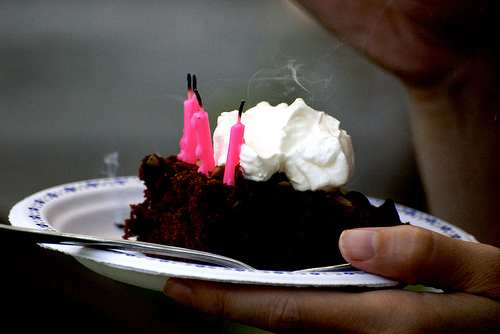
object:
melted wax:
[176, 132, 185, 160]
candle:
[176, 68, 193, 161]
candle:
[192, 89, 212, 176]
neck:
[411, 84, 499, 235]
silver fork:
[5, 216, 376, 293]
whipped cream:
[212, 96, 354, 192]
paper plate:
[8, 172, 494, 289]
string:
[235, 100, 250, 121]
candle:
[221, 99, 244, 186]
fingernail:
[340, 226, 383, 262]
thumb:
[335, 222, 496, 292]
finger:
[165, 277, 478, 333]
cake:
[118, 94, 405, 259]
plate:
[6, 166, 486, 299]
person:
[163, 0, 498, 332]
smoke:
[173, 14, 382, 137]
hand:
[159, 226, 500, 331]